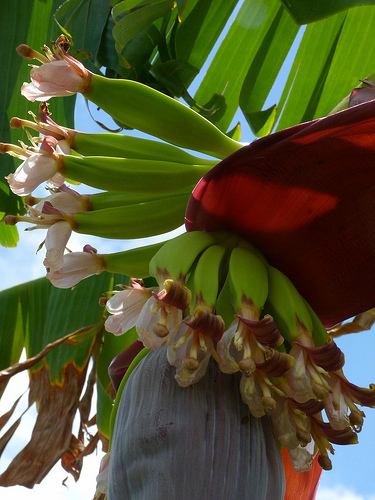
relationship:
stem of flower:
[116, 86, 179, 119] [16, 62, 100, 94]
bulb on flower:
[4, 42, 48, 70] [16, 62, 100, 94]